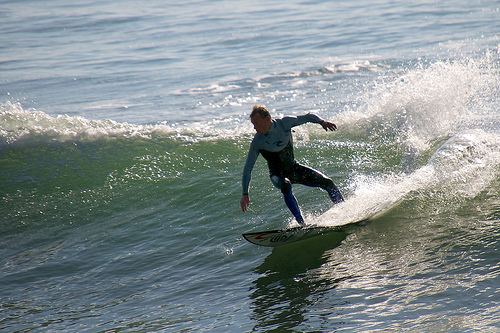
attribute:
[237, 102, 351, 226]
man — making wake, surfing, surfer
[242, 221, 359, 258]
surfboard — white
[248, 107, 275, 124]
hair — brown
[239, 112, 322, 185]
top — blue, black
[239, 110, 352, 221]
wetsuit — black, blue, white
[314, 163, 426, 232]
wake — white, spraying in air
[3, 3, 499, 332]
water — light blue, blue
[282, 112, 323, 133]
arm — extended, raised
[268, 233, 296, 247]
graphic design — black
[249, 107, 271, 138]
head — turned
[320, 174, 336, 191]
knee — bent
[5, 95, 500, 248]
wave — white, blue